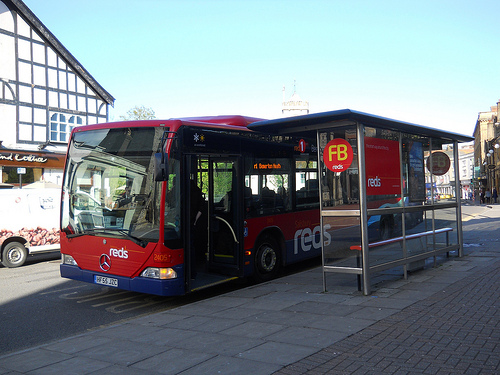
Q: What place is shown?
A: It is a street.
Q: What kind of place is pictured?
A: It is a street.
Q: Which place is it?
A: It is a street.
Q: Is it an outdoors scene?
A: Yes, it is outdoors.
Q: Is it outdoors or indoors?
A: It is outdoors.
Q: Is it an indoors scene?
A: No, it is outdoors.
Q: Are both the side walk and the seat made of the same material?
A: No, the side walk is made of concrete and the seat is made of metal.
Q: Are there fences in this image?
A: No, there are no fences.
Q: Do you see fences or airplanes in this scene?
A: No, there are no fences or airplanes.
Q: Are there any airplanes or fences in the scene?
A: No, there are no fences or airplanes.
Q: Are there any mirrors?
A: Yes, there is a mirror.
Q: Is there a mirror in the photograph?
A: Yes, there is a mirror.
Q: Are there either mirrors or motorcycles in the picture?
A: Yes, there is a mirror.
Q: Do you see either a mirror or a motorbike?
A: Yes, there is a mirror.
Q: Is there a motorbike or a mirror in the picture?
A: Yes, there is a mirror.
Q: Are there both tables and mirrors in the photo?
A: No, there is a mirror but no tables.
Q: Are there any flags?
A: No, there are no flags.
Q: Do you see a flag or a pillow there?
A: No, there are no flags or pillows.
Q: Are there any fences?
A: No, there are no fences.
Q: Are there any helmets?
A: No, there are no helmets.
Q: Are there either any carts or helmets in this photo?
A: No, there are no helmets or carts.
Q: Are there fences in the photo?
A: No, there are no fences.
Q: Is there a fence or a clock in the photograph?
A: No, there are no fences or clocks.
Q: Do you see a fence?
A: No, there are no fences.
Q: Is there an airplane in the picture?
A: No, there are no airplanes.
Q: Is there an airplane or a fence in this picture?
A: No, there are no airplanes or fences.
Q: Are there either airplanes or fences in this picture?
A: No, there are no airplanes or fences.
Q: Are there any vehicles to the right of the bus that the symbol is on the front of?
A: No, the vehicle is to the left of the bus.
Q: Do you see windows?
A: Yes, there is a window.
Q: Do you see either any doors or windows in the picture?
A: Yes, there is a window.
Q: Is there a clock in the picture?
A: No, there are no clocks.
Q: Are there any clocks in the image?
A: No, there are no clocks.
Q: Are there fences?
A: No, there are no fences.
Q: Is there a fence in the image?
A: No, there are no fences.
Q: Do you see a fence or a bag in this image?
A: No, there are no fences or bags.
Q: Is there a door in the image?
A: Yes, there is a door.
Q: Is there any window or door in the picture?
A: Yes, there is a door.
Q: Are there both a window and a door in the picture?
A: Yes, there are both a door and a window.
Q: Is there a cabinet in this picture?
A: No, there are no cabinets.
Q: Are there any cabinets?
A: No, there are no cabinets.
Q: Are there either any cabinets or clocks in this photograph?
A: No, there are no cabinets or clocks.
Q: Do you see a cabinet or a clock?
A: No, there are no cabinets or clocks.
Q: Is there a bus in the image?
A: Yes, there is a bus.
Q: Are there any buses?
A: Yes, there is a bus.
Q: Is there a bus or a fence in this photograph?
A: Yes, there is a bus.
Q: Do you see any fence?
A: No, there are no fences.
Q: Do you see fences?
A: No, there are no fences.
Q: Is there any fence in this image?
A: No, there are no fences.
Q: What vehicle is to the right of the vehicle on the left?
A: The vehicle is a bus.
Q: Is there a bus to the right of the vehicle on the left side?
A: Yes, there is a bus to the right of the vehicle.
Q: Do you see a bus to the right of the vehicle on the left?
A: Yes, there is a bus to the right of the vehicle.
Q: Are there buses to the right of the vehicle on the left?
A: Yes, there is a bus to the right of the vehicle.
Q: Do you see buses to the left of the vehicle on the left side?
A: No, the bus is to the right of the vehicle.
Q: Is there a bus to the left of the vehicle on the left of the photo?
A: No, the bus is to the right of the vehicle.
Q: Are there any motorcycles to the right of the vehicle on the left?
A: No, there is a bus to the right of the vehicle.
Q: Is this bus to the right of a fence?
A: No, the bus is to the right of the vehicle.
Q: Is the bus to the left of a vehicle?
A: No, the bus is to the right of a vehicle.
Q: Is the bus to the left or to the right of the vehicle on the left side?
A: The bus is to the right of the vehicle.